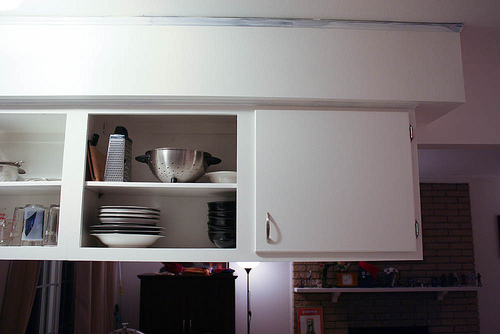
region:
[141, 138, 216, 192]
Black and silver colander.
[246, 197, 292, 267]
Silver handle for cabinet.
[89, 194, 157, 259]
Bowls and plates stacked in cupboard.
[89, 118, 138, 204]
Silver and black cheese shredder.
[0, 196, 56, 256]
Blue white clear glass.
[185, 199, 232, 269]
Black bowls in cupboard.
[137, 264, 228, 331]
Black and silver cupboard.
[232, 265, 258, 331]
White lamp with black stand.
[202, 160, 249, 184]
White bowl in cupboard.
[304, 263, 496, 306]
White shelf with items on it.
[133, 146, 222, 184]
Metal strainer with black handles.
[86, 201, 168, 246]
Stacked up plates in a cabinet.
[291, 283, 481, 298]
White shelf over a fireplace.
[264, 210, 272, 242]
Silver handle on a white cabinet door.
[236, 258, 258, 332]
Tall thin lamp that is turned on.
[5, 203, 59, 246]
Four glasses in the left cabinet.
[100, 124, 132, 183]
Silver grater with black handle next to a metal strainer.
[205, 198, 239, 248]
Black shiny bowls stacked up in a cabinet.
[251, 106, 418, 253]
White cabinet door with silver handle.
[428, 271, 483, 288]
Little figures of people on the shelf of the fireplace.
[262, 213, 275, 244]
a handle on a cabinet door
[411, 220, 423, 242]
a hinge on a door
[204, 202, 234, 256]
a stack of bowls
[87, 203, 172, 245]
a stack of plates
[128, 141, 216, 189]
a metal colander on a shelf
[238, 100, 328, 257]
a white cabinet door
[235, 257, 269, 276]
a light under a cabinet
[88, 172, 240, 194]
shelf in a cabinet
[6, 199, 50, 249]
a mug on a shelf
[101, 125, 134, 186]
a metal grater on a shelf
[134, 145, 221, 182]
silver colander with black handles on elevated white shelf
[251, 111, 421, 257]
white kitchen cabinet with silver handle and hinges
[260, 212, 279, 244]
silver kitchen cabinet door handle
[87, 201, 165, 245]
stack of white bowls with blue accents on elevated kitchen shelf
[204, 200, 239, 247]
stack of black bowls on shelf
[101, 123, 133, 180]
silver cheese grater with black handle on shelf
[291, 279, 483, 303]
white mantle on brick fireplace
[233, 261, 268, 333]
tall floor lamp with white shade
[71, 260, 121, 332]
tan curtain panel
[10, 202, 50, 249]
clear drinking glass with blue design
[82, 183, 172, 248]
stack of white plates in a cabinet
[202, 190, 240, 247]
stack of black bowls in a cabinet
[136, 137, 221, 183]
metal containet with holes on it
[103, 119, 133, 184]
silver grater in a cabinet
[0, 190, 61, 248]
group of clear glasses in a cabinet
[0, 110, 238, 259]
white cabinet filled with lots of dishes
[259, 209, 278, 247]
silver handle of a cabinet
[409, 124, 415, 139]
silver hinges of a white cabinet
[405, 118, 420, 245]
two silver hinges on the white cabinet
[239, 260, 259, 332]
tall black and white lamp